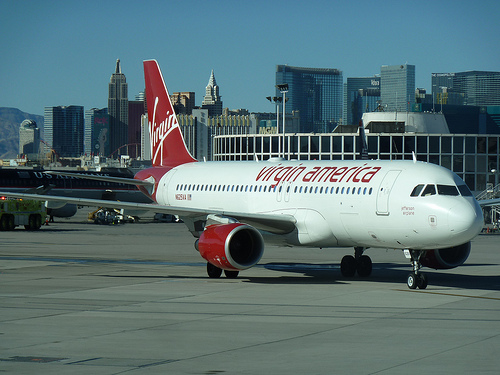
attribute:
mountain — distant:
[0, 103, 43, 157]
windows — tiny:
[172, 182, 375, 199]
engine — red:
[196, 221, 266, 269]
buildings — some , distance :
[43, 58, 130, 159]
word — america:
[300, 160, 381, 186]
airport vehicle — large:
[11, 62, 487, 297]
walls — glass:
[194, 132, 496, 167]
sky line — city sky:
[235, 53, 480, 148]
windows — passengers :
[179, 178, 386, 205]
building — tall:
[197, 64, 223, 117]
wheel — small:
[404, 268, 433, 292]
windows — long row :
[183, 162, 380, 199]